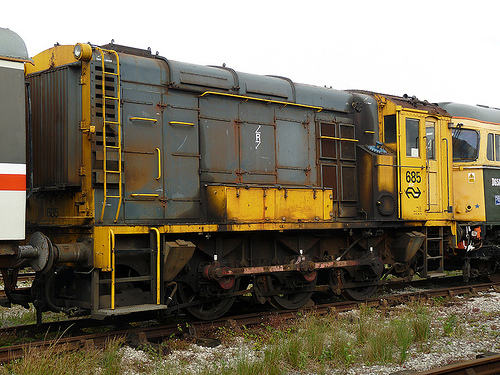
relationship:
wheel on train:
[176, 235, 238, 318] [0, 29, 498, 321]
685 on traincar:
[404, 167, 423, 182] [20, 39, 450, 316]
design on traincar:
[236, 103, 281, 163] [34, 44, 453, 295]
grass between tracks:
[0, 296, 462, 373] [418, 351, 498, 373]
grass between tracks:
[0, 296, 462, 373] [0, 275, 497, 362]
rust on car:
[262, 190, 269, 219] [24, 38, 441, 321]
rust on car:
[232, 122, 245, 183] [24, 38, 441, 321]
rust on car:
[27, 79, 64, 176] [24, 38, 441, 321]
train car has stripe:
[2, 25, 52, 252] [0, 174, 27, 191]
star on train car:
[469, 200, 484, 210] [444, 100, 499, 238]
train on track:
[0, 29, 498, 321] [2, 271, 494, 362]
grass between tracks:
[0, 296, 462, 373] [0, 271, 498, 373]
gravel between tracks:
[111, 286, 500, 375] [0, 271, 498, 373]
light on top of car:
[71, 42, 94, 60] [24, 38, 441, 321]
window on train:
[400, 111, 420, 158] [24, 51, 486, 312]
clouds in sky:
[1, 2, 499, 105] [0, 0, 497, 122]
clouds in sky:
[1, 2, 499, 105] [25, 4, 492, 97]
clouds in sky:
[1, 2, 499, 105] [2, 1, 499, 81]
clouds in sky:
[1, 2, 499, 105] [3, 6, 480, 76]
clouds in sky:
[1, 2, 499, 105] [314, 32, 480, 75]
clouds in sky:
[1, 2, 499, 105] [0, 4, 498, 109]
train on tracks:
[0, 29, 498, 321] [0, 275, 497, 362]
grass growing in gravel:
[0, 296, 462, 373] [294, 300, 474, 372]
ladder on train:
[94, 46, 121, 222] [0, 29, 498, 321]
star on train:
[475, 203, 481, 209] [0, 29, 498, 321]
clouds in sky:
[1, 2, 499, 105] [321, 4, 442, 54]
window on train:
[406, 117, 419, 158] [0, 29, 498, 321]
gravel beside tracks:
[241, 255, 488, 364] [142, 254, 492, 349]